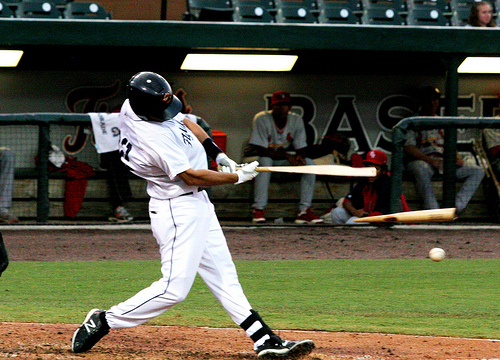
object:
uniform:
[102, 95, 278, 341]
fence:
[0, 110, 151, 225]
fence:
[388, 115, 500, 226]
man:
[404, 91, 486, 224]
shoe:
[257, 335, 314, 360]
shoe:
[70, 308, 111, 353]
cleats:
[222, 202, 322, 218]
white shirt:
[248, 109, 308, 149]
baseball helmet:
[127, 71, 183, 121]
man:
[317, 149, 408, 225]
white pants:
[105, 192, 270, 349]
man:
[249, 89, 317, 226]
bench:
[50, 165, 485, 221]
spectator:
[464, 0, 499, 28]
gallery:
[0, 0, 500, 360]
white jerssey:
[118, 98, 208, 200]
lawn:
[333, 281, 500, 333]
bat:
[217, 163, 379, 178]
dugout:
[2, 0, 499, 219]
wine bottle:
[427, 247, 445, 262]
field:
[0, 254, 500, 327]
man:
[67, 70, 317, 360]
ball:
[428, 247, 446, 262]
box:
[70, 308, 117, 360]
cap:
[272, 90, 293, 107]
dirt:
[0, 319, 500, 360]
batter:
[255, 164, 379, 179]